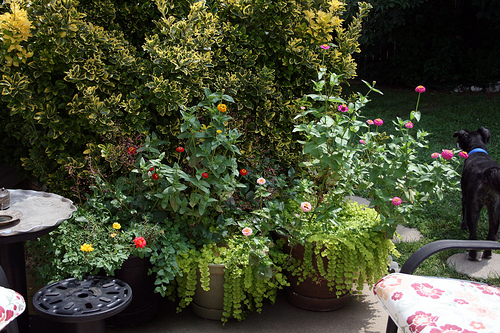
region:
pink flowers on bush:
[319, 82, 387, 142]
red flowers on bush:
[125, 139, 215, 200]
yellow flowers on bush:
[71, 213, 128, 265]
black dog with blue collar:
[450, 114, 497, 233]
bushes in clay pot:
[7, 85, 296, 309]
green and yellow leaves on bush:
[1, 3, 362, 142]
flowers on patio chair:
[338, 223, 496, 330]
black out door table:
[3, 184, 78, 291]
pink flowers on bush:
[216, 218, 255, 243]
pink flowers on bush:
[238, 210, 271, 255]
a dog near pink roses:
[447, 120, 498, 264]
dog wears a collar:
[450, 119, 497, 179]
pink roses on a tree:
[314, 36, 479, 211]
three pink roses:
[241, 173, 318, 240]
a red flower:
[122, 232, 156, 256]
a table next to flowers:
[2, 174, 82, 244]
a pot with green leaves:
[171, 228, 261, 322]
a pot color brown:
[277, 198, 373, 318]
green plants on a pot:
[276, 210, 376, 311]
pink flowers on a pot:
[286, 28, 373, 303]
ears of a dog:
[452, 123, 493, 141]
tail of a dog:
[474, 154, 496, 186]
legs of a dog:
[442, 201, 495, 265]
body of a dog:
[457, 157, 497, 201]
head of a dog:
[444, 108, 498, 161]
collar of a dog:
[465, 144, 493, 161]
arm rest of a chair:
[354, 233, 497, 280]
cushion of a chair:
[365, 253, 493, 318]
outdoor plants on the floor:
[76, 34, 386, 324]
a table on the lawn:
[5, 187, 78, 314]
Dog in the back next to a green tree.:
[463, 124, 480, 233]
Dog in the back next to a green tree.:
[15, 59, 208, 83]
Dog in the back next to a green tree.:
[346, 33, 446, 77]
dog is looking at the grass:
[437, 113, 499, 259]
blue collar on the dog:
[457, 145, 497, 168]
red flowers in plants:
[101, 130, 268, 254]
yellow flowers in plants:
[52, 94, 279, 249]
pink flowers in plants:
[315, 36, 470, 214]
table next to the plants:
[3, 178, 74, 328]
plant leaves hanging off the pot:
[158, 247, 280, 329]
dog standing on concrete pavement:
[443, 103, 498, 266]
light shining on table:
[10, 182, 76, 244]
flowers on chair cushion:
[366, 249, 496, 331]